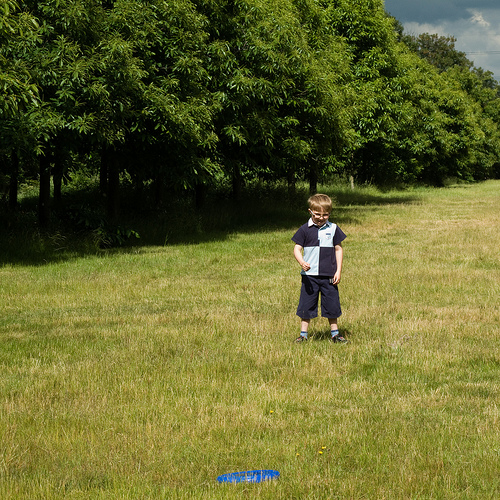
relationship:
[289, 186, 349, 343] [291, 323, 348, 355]
boy wearing shoes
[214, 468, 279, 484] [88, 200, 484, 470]
frisbee in grass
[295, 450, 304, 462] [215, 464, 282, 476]
flower closest to frisbee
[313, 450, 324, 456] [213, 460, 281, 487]
flower closest to frisbee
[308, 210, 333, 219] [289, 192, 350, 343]
glasses on boy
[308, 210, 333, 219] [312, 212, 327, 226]
glasses on face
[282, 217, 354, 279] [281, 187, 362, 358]
shirt on boy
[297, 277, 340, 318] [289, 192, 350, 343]
shorts on boy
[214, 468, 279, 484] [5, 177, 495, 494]
frisbee on grass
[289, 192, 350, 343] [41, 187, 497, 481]
boy on grass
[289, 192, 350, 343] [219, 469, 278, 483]
boy playing frisbee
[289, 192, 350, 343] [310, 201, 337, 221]
boy wears glasses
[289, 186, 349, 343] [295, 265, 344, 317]
boy in shorts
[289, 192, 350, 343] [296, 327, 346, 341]
boy wearing socks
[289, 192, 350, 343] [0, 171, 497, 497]
boy standing in field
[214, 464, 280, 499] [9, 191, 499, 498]
frisbee on ground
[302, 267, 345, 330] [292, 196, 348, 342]
black shorts worn by child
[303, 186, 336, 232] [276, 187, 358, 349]
head of child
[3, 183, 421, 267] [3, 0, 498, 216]
shadow of trees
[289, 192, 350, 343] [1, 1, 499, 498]
boy in field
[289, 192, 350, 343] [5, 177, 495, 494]
boy standing in grass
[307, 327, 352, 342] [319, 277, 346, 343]
shadow on leg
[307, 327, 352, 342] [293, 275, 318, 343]
shadow on leg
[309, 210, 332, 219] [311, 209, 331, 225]
glasses on face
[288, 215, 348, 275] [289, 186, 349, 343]
checkered shirt on boy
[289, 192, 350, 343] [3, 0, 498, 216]
boy in front of trees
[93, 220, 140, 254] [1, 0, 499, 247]
plant near trees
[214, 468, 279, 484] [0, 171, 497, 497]
frisbee in grass field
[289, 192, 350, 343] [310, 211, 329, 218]
boy has glasses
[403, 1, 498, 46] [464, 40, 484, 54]
sky filled with clouds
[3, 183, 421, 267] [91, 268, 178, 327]
shadow are on ground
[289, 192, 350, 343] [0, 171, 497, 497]
boy standing in a field